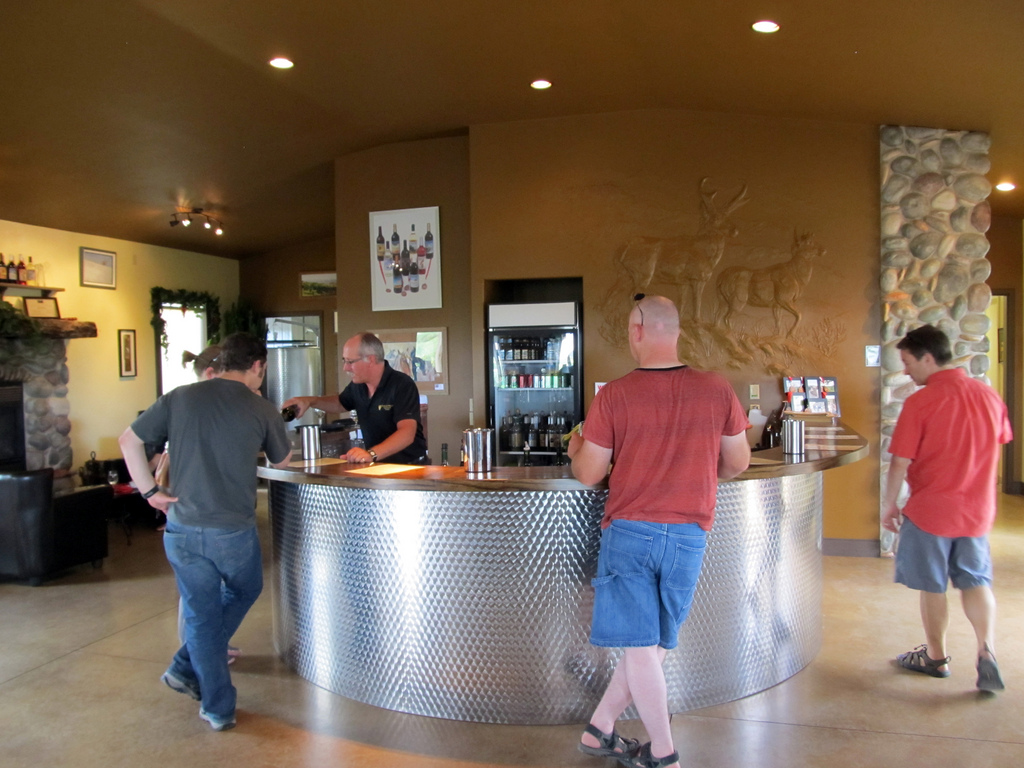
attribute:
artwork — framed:
[354, 197, 458, 317]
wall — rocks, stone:
[875, 123, 1000, 585]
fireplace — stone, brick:
[0, 313, 99, 533]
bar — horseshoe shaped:
[271, 382, 873, 713]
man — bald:
[560, 286, 745, 762]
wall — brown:
[450, 109, 886, 523]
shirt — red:
[570, 360, 744, 529]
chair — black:
[4, 457, 116, 570]